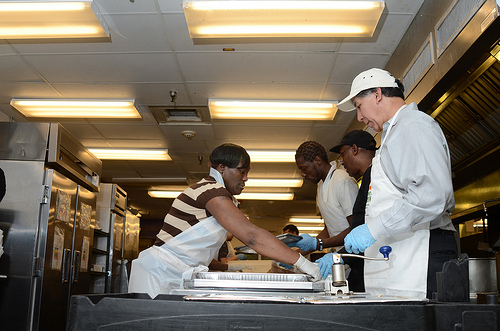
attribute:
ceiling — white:
[2, 0, 447, 199]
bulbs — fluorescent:
[183, 4, 381, 41]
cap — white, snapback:
[330, 65, 405, 105]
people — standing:
[156, 65, 459, 296]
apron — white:
[362, 149, 431, 288]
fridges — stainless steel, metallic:
[2, 119, 138, 328]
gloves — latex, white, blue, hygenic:
[294, 253, 332, 281]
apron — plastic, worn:
[143, 221, 227, 286]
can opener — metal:
[326, 246, 392, 293]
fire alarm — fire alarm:
[177, 126, 202, 142]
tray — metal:
[231, 232, 302, 253]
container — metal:
[194, 268, 315, 280]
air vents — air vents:
[154, 105, 207, 124]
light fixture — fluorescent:
[0, 1, 113, 43]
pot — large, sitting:
[467, 256, 500, 294]